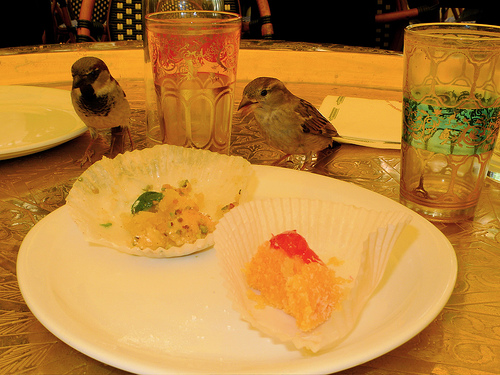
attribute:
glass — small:
[147, 8, 250, 160]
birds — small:
[64, 51, 344, 170]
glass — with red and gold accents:
[143, 8, 241, 154]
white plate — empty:
[78, 145, 394, 353]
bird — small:
[62, 54, 156, 156]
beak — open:
[234, 98, 258, 121]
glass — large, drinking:
[397, 23, 497, 220]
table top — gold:
[10, 51, 498, 368]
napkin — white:
[316, 85, 418, 157]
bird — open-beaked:
[227, 68, 347, 178]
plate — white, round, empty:
[16, 142, 461, 374]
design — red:
[150, 31, 236, 78]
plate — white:
[18, 161, 465, 372]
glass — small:
[376, 70, 481, 219]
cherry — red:
[274, 230, 319, 261]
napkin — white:
[324, 89, 409, 151]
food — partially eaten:
[115, 115, 372, 322]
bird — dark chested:
[69, 55, 137, 167]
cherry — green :
[196, 211, 328, 286]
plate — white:
[72, 255, 211, 375]